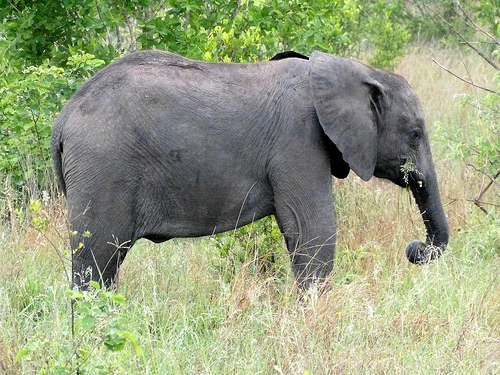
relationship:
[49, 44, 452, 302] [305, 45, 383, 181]
elephant has right ear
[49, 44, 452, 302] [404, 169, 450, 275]
elephant has trunk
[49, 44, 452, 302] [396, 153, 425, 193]
elephant eating leaves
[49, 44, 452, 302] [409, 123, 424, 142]
elephant has right eye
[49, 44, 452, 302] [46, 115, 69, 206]
elephant has tail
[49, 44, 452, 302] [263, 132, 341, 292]
elephant has front leg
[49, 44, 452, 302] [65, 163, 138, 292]
elephant has hind leg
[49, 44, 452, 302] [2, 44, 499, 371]
elephant standing in grass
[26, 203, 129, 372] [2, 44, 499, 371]
tree growing in grass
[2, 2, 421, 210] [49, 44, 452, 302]
trees are behind elephant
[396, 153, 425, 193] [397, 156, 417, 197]
leaves are in mouth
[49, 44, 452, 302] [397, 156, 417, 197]
elephant has mouth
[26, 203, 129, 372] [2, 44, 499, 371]
tree in grass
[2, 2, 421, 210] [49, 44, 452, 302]
trees are beside elephant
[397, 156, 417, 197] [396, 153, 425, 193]
mouth filled with leaves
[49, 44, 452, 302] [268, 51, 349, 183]
elephant has left ear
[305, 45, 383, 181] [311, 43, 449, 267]
right ear on head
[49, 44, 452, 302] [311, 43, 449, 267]
elephant has head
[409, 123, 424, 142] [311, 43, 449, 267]
right eye on side of head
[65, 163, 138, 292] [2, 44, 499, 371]
hind leg in grass